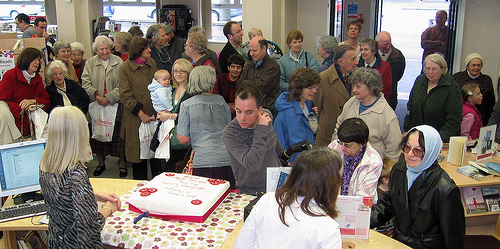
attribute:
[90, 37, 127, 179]
person — standing up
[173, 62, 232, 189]
person — standing up